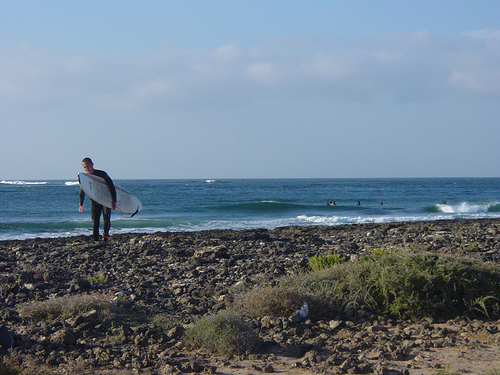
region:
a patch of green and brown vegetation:
[19, 287, 113, 322]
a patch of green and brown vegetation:
[187, 308, 258, 355]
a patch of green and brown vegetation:
[242, 288, 298, 315]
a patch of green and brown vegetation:
[286, 246, 491, 318]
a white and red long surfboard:
[76, 171, 143, 214]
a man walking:
[77, 156, 114, 243]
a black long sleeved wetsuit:
[77, 171, 119, 237]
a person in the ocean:
[355, 197, 361, 207]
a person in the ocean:
[353, 199, 360, 206]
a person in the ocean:
[327, 199, 337, 207]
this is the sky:
[223, 115, 264, 146]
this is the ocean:
[4, 170, 499, 245]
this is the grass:
[227, 225, 494, 333]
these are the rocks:
[93, 259, 162, 318]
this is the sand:
[446, 351, 472, 373]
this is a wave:
[220, 177, 334, 221]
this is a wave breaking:
[0, 165, 62, 193]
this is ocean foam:
[432, 214, 449, 219]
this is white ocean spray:
[454, 196, 470, 216]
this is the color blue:
[237, 153, 256, 163]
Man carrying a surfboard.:
[74, 157, 142, 243]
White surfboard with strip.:
[75, 172, 147, 215]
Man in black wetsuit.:
[75, 149, 117, 241]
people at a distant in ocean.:
[327, 199, 384, 206]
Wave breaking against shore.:
[435, 203, 497, 215]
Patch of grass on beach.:
[275, 247, 464, 313]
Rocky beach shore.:
[174, 241, 284, 273]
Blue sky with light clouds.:
[156, 21, 416, 153]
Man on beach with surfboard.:
[72, 157, 142, 240]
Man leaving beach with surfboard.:
[74, 156, 140, 245]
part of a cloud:
[247, 62, 289, 132]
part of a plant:
[301, 271, 330, 299]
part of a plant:
[185, 305, 210, 332]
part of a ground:
[165, 238, 200, 279]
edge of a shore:
[215, 218, 256, 236]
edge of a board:
[68, 177, 103, 219]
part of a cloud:
[205, 160, 245, 173]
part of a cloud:
[223, 55, 292, 118]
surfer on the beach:
[54, 131, 147, 273]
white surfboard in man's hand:
[120, 172, 141, 233]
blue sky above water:
[253, 110, 318, 167]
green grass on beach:
[315, 239, 415, 341]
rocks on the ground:
[160, 225, 222, 299]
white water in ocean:
[449, 197, 478, 228]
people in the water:
[318, 194, 392, 231]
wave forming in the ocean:
[242, 190, 280, 227]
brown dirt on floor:
[418, 324, 476, 374]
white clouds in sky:
[215, 21, 344, 129]